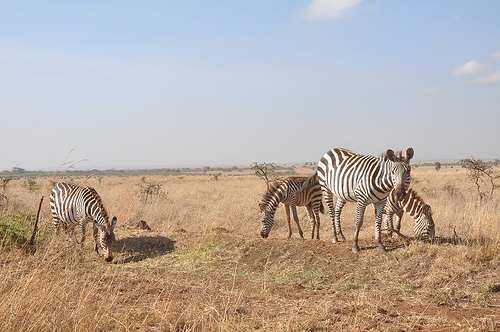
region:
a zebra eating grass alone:
[49, 177, 124, 264]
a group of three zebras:
[257, 146, 439, 253]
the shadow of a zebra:
[114, 229, 177, 264]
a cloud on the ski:
[308, 0, 361, 26]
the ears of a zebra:
[379, 143, 417, 163]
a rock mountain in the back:
[10, 164, 27, 175]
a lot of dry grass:
[16, 178, 491, 236]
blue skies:
[7, 3, 495, 173]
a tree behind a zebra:
[247, 156, 279, 192]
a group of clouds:
[453, 46, 498, 83]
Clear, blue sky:
[0, 0, 499, 167]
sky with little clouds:
[1, 0, 496, 170]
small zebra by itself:
[48, 184, 118, 261]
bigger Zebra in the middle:
[317, 147, 414, 251]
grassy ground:
[1, 168, 498, 330]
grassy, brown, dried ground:
[0, 167, 499, 328]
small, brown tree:
[462, 158, 498, 200]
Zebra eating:
[259, 176, 318, 236]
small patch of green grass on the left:
[0, 205, 41, 248]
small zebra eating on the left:
[49, 181, 117, 261]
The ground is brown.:
[282, 255, 380, 320]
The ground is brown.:
[212, 202, 352, 329]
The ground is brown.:
[298, 302, 350, 329]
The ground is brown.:
[272, 268, 327, 326]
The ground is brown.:
[254, 240, 338, 317]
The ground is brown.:
[264, 242, 295, 327]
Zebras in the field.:
[51, 162, 468, 245]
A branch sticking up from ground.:
[9, 195, 46, 241]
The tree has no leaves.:
[246, 154, 293, 189]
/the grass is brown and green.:
[206, 243, 402, 318]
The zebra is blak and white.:
[41, 168, 146, 291]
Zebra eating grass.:
[228, 161, 328, 249]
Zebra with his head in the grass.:
[400, 175, 453, 236]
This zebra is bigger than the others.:
[300, 138, 434, 230]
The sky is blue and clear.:
[88, 15, 413, 155]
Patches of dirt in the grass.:
[346, 294, 456, 319]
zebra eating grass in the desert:
[48, 182, 120, 262]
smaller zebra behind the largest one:
[259, 175, 323, 239]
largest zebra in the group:
[316, 145, 413, 251]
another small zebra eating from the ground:
[389, 192, 436, 241]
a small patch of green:
[3, 222, 37, 249]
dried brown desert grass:
[3, 255, 139, 323]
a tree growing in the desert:
[461, 156, 497, 198]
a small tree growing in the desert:
[251, 162, 283, 189]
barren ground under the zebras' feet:
[261, 237, 410, 267]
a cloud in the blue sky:
[451, 50, 498, 87]